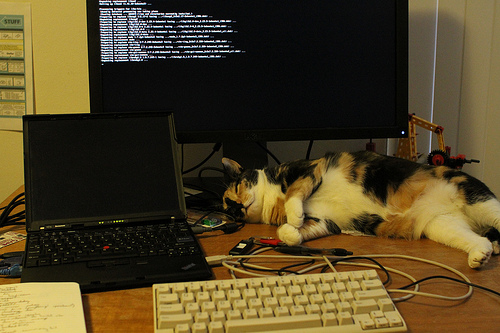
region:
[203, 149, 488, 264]
a calico cat sleeping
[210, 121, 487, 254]
a cat sleeping on a desk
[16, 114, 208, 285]
a black laptop computer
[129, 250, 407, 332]
a white computer keyboard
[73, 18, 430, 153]
a black computer monitor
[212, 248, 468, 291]
several cables and cords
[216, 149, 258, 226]
a cat with one black eye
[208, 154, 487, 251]
a white, black and orange cat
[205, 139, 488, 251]
a cat laying on a desk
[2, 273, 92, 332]
a note book with writing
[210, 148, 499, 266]
a black white and brown cat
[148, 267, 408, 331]
a white computer keyboard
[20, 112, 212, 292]
a black computer laptop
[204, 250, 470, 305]
a white USB cable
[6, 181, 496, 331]
a brown computer desk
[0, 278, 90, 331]
a handwritten piece of paper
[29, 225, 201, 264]
a black computer keyboard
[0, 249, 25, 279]
a DVD disc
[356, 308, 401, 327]
a set of computer arrow keys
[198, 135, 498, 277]
A calico cat is napping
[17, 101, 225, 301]
a small black laptop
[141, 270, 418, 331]
a keyboard for the computer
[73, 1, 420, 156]
a computer monitor with scripts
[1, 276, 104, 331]
a book with handwriting on the pages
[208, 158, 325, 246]
This cat is totally relaxed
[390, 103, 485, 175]
a toy construction vehicle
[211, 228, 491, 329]
a bunch of wires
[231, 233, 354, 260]
an ink pen and a thumb drive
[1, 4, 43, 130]
a paper on the wall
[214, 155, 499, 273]
calico cat laying on a desk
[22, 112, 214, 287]
small black notebook computer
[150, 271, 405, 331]
white desktop keyboard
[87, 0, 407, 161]
big black computer monitor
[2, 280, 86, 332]
notepad with notes on the desk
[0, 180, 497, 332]
brown wooden desk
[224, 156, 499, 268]
cat asleep on its side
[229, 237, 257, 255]
USB thumb d4ive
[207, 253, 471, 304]
white USB cable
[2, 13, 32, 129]
chart on the wall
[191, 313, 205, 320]
key on the keyboard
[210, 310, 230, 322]
key on the keyboard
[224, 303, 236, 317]
key on the keyboard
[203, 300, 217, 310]
key on the keyboard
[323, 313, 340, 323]
key on the keyboard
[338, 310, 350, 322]
key on the keyboard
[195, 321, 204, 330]
key on the keyboard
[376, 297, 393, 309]
key on the keyboard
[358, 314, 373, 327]
key on the keyboard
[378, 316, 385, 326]
key on the keyboard